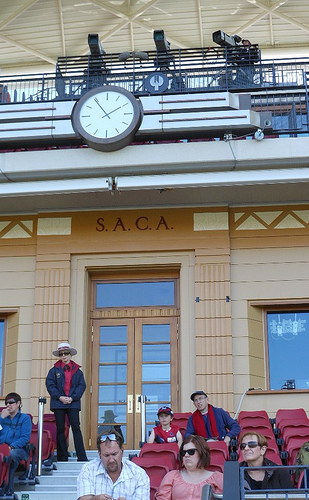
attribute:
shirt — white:
[73, 455, 150, 499]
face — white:
[87, 92, 122, 133]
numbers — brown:
[117, 99, 134, 126]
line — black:
[114, 125, 121, 134]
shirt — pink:
[154, 469, 222, 499]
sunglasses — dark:
[58, 351, 69, 354]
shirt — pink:
[156, 467, 226, 499]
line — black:
[114, 93, 119, 100]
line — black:
[104, 91, 110, 100]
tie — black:
[62, 364, 70, 371]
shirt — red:
[59, 358, 73, 387]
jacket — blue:
[0, 411, 31, 447]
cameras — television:
[62, 25, 294, 91]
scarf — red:
[50, 351, 91, 375]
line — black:
[84, 103, 92, 109]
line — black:
[91, 97, 114, 122]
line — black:
[90, 96, 122, 121]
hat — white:
[52, 336, 79, 376]